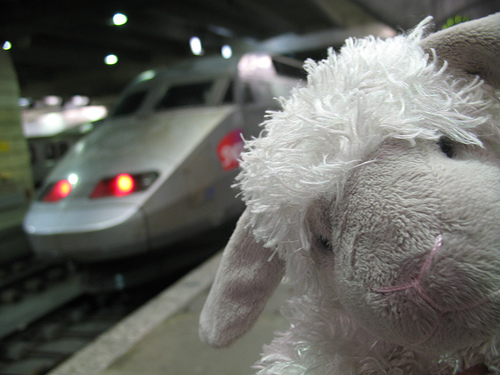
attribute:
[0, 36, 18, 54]
light — white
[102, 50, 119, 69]
light — white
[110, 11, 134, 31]
light — white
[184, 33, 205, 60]
light — white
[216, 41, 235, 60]
light — white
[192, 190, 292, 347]
ear — teddybear's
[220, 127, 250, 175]
mark — red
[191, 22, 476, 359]
toy — long strands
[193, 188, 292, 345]
ears — long 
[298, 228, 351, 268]
eyes — dark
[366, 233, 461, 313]
configuration — pink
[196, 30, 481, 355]
head — toys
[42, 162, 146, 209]
lights — on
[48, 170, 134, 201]
lights — red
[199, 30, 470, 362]
lamb — white, stuffed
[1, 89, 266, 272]
train — silver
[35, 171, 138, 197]
headlights — red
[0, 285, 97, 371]
tracks — train tracks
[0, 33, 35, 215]
column — brick, in the background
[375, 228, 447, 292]
nose — pink threaded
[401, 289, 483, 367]
mouth — pink threaded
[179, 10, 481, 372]
lamb — stuffed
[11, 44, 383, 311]
train — steel, grey